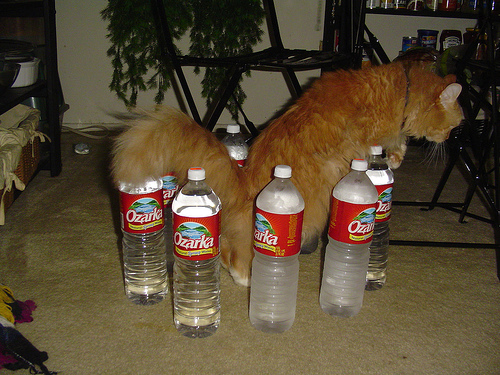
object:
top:
[272, 164, 294, 179]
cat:
[104, 56, 465, 264]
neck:
[394, 62, 424, 134]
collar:
[398, 59, 413, 132]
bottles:
[114, 146, 397, 340]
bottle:
[172, 168, 223, 341]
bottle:
[116, 181, 171, 306]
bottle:
[249, 164, 306, 332]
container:
[415, 28, 440, 50]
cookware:
[0, 44, 71, 179]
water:
[247, 160, 302, 332]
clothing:
[0, 283, 60, 374]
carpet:
[329, 322, 498, 375]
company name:
[173, 220, 215, 261]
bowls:
[0, 61, 21, 96]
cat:
[109, 61, 466, 286]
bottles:
[166, 165, 222, 339]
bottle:
[360, 144, 395, 292]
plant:
[94, 0, 267, 137]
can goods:
[360, 0, 499, 67]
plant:
[87, 0, 268, 161]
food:
[399, 35, 421, 61]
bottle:
[245, 165, 305, 333]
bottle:
[316, 157, 372, 318]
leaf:
[152, 44, 165, 56]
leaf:
[116, 89, 127, 102]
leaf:
[109, 75, 121, 91]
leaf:
[143, 76, 156, 87]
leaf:
[134, 5, 147, 24]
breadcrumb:
[403, 46, 468, 78]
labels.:
[250, 206, 306, 259]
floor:
[123, 326, 301, 373]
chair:
[146, 0, 357, 132]